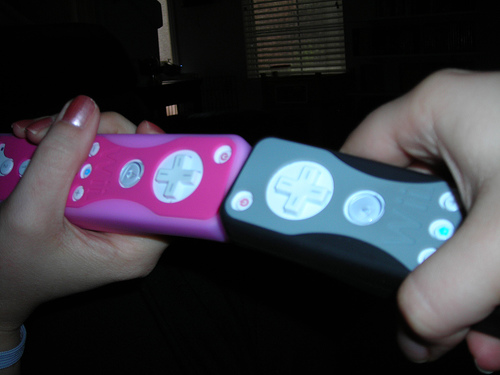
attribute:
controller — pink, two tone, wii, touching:
[1, 128, 254, 251]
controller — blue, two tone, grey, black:
[217, 130, 500, 344]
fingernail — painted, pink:
[61, 93, 98, 135]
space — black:
[22, 240, 476, 374]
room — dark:
[2, 1, 499, 374]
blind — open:
[237, 1, 352, 78]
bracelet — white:
[0, 321, 33, 373]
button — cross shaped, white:
[262, 155, 337, 223]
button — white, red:
[228, 186, 257, 216]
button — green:
[427, 212, 457, 245]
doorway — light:
[146, 1, 195, 135]